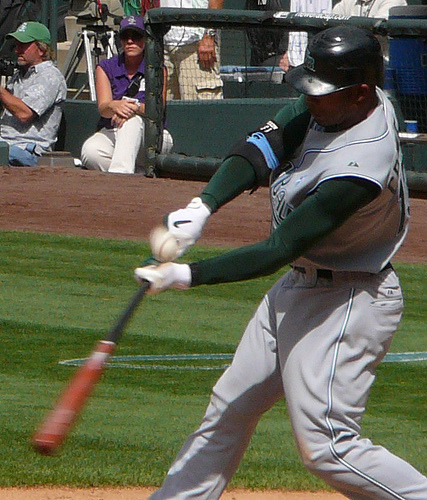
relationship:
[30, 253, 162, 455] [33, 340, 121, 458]
baseball bat has color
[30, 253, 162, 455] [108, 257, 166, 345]
baseball bat has color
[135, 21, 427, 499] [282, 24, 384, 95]
baseball player has helmet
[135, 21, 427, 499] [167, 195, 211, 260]
baseball player wearing glove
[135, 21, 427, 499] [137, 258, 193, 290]
baseball player wearing glove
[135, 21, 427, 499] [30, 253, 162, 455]
baseball player swinging baseball bat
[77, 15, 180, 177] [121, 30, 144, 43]
woman wearing sunglasses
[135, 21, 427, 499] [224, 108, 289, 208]
baseball player wearing arm brace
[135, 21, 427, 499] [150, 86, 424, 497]
baseball player has uniform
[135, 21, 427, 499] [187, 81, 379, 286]
baseball player has under shirt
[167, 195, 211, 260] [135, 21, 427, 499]
glove on baseball player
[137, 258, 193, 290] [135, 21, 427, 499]
glove on baseball player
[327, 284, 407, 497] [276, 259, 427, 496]
stripe on leg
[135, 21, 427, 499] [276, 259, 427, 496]
baseball player has leg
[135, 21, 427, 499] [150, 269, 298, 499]
baseball player swinging against leg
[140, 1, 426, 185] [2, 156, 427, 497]
railing near baseball field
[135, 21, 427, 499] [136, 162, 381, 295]
baseball player has arm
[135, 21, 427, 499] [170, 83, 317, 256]
baseball player has arm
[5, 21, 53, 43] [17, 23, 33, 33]
ball cap with writing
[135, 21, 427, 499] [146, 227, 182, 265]
baseball player swinging to hit baseball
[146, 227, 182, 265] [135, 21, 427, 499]
baseball coming past baseball player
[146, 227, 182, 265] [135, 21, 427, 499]
baseball past baseball player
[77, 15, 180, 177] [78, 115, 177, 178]
woman in pants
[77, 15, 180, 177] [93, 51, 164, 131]
woman in shirt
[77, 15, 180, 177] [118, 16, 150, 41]
woman in ball cap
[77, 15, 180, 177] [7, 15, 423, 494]
woman watching game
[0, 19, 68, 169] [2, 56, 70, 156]
man wearing shirt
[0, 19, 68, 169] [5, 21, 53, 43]
man wearing ball cap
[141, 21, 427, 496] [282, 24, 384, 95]
baseball player has helmet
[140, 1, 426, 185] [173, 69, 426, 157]
railing entrance to dugout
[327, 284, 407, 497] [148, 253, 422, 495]
stripe on pants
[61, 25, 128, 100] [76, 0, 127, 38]
tripod for camera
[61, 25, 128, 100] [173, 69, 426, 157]
tripod behind dugout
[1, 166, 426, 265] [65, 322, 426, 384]
patch at home base